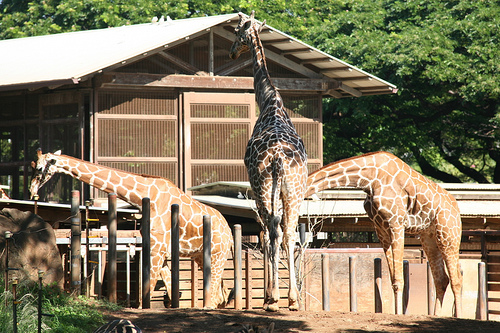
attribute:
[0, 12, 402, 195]
building — brown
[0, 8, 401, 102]
roof — silver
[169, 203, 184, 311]
pole — metal, tall, planted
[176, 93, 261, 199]
gate — wooden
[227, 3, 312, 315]
giraffe — standing, spotted, tall, brown, white, large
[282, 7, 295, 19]
bird — in tree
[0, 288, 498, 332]
ground — dirty, existing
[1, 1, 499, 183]
tree — in background, large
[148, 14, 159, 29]
bird — white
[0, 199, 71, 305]
boulder — huge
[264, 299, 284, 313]
hoof — existing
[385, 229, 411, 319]
leg — existing